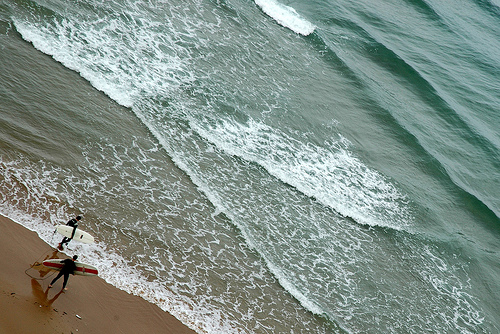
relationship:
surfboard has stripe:
[26, 254, 100, 281] [46, 258, 95, 274]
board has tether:
[48, 222, 95, 251] [46, 222, 60, 245]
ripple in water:
[0, 0, 499, 333] [330, 33, 499, 211]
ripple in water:
[0, 0, 499, 333] [337, 11, 497, 123]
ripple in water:
[0, 0, 499, 333] [339, 4, 499, 134]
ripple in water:
[213, 129, 334, 214] [102, 13, 474, 296]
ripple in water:
[0, 0, 499, 333] [157, 42, 478, 289]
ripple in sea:
[0, 0, 499, 333] [0, 0, 499, 332]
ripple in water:
[0, 0, 499, 333] [119, 64, 433, 289]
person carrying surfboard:
[53, 209, 85, 249] [51, 224, 97, 248]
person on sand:
[51, 252, 79, 293] [0, 292, 93, 326]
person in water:
[53, 209, 85, 249] [18, 140, 206, 248]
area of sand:
[5, 219, 157, 324] [5, 216, 175, 323]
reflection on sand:
[25, 273, 62, 312] [5, 216, 175, 323]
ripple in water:
[0, 0, 499, 333] [10, 4, 466, 322]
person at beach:
[46, 253, 78, 292] [0, 203, 203, 331]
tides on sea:
[334, 19, 484, 144] [2, 2, 484, 250]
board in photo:
[50, 223, 95, 244] [2, 1, 483, 331]